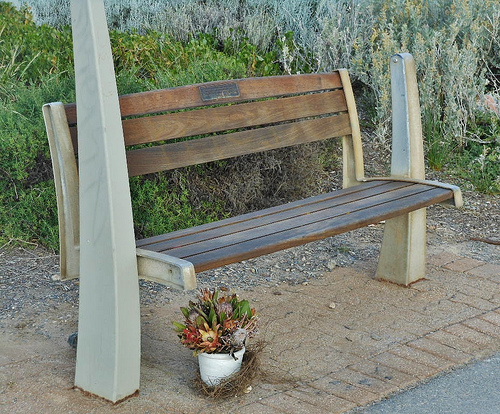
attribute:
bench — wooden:
[35, 66, 454, 323]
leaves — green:
[174, 290, 291, 378]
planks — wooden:
[40, 66, 345, 120]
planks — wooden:
[65, 85, 357, 164]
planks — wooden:
[68, 109, 355, 186]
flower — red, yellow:
[197, 321, 223, 352]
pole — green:
[53, 0, 163, 413]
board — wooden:
[60, 62, 343, 118]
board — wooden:
[70, 87, 349, 154]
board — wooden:
[120, 114, 363, 179]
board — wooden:
[183, 190, 446, 267]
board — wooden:
[145, 177, 380, 251]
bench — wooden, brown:
[38, 59, 480, 403]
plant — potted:
[180, 287, 256, 388]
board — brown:
[134, 176, 389, 248]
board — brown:
[140, 179, 414, 254]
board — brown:
[164, 181, 435, 263]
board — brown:
[187, 187, 449, 279]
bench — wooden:
[41, 64, 461, 295]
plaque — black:
[194, 73, 241, 102]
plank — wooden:
[180, 185, 453, 273]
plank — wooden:
[165, 176, 427, 259]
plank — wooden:
[144, 179, 394, 251]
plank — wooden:
[131, 172, 391, 248]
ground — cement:
[366, 353, 493, 411]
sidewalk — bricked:
[2, 134, 496, 411]